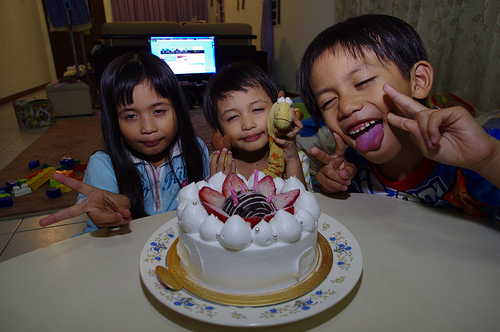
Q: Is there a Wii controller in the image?
A: No, there are no Wii controllers.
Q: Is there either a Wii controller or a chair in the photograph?
A: No, there are no Wii controllers or chairs.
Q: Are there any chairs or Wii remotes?
A: No, there are no Wii remotes or chairs.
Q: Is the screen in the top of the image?
A: Yes, the screen is in the top of the image.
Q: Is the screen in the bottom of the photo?
A: No, the screen is in the top of the image.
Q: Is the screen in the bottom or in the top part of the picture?
A: The screen is in the top of the image.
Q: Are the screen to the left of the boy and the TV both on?
A: Yes, both the screen and the TV are on.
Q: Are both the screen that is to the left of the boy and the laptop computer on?
A: Yes, both the screen and the laptop computer are on.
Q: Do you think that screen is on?
A: Yes, the screen is on.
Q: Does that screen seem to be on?
A: Yes, the screen is on.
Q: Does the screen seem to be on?
A: Yes, the screen is on.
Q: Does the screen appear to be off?
A: No, the screen is on.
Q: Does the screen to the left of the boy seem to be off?
A: No, the screen is on.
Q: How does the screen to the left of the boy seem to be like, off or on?
A: The screen is on.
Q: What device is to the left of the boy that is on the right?
A: The device is a screen.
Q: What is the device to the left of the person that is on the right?
A: The device is a screen.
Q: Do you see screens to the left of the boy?
A: Yes, there is a screen to the left of the boy.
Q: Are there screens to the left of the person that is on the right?
A: Yes, there is a screen to the left of the boy.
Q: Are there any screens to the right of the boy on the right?
A: No, the screen is to the left of the boy.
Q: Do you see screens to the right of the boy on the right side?
A: No, the screen is to the left of the boy.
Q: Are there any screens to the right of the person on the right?
A: No, the screen is to the left of the boy.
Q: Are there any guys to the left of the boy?
A: No, there is a screen to the left of the boy.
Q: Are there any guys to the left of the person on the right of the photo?
A: No, there is a screen to the left of the boy.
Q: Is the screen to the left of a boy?
A: Yes, the screen is to the left of a boy.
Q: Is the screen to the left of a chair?
A: No, the screen is to the left of a boy.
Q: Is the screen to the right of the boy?
A: No, the screen is to the left of the boy.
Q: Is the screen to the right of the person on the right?
A: No, the screen is to the left of the boy.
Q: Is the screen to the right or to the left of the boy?
A: The screen is to the left of the boy.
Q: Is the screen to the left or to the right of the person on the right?
A: The screen is to the left of the boy.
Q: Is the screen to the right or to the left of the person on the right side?
A: The screen is to the left of the boy.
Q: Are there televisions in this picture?
A: Yes, there is a television.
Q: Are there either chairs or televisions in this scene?
A: Yes, there is a television.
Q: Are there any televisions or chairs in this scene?
A: Yes, there is a television.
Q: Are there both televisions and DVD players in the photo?
A: No, there is a television but no DVD players.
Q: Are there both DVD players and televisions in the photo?
A: No, there is a television but no DVD players.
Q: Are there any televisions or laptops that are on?
A: Yes, the television is on.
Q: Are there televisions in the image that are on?
A: Yes, there is a television that is on.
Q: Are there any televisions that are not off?
A: Yes, there is a television that is on.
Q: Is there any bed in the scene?
A: No, there are no beds.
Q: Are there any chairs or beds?
A: No, there are no beds or chairs.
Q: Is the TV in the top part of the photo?
A: Yes, the TV is in the top of the image.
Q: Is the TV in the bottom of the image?
A: No, the TV is in the top of the image.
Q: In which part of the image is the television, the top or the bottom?
A: The television is in the top of the image.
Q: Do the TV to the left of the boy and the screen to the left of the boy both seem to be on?
A: Yes, both the TV and the screen are on.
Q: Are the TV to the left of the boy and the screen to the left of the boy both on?
A: Yes, both the TV and the screen are on.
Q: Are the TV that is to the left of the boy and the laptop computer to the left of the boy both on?
A: Yes, both the television and the laptop are on.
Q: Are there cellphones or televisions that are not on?
A: No, there is a television but it is on.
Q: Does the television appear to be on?
A: Yes, the television is on.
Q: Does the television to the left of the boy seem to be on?
A: Yes, the TV is on.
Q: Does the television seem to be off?
A: No, the television is on.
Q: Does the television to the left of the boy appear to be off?
A: No, the television is on.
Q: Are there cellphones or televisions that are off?
A: No, there is a television but it is on.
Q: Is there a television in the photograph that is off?
A: No, there is a television but it is on.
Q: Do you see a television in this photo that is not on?
A: No, there is a television but it is on.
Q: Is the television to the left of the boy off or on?
A: The television is on.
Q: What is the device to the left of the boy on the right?
A: The device is a television.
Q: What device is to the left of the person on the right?
A: The device is a television.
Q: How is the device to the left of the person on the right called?
A: The device is a television.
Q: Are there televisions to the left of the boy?
A: Yes, there is a television to the left of the boy.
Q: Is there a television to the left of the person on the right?
A: Yes, there is a television to the left of the boy.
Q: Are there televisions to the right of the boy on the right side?
A: No, the television is to the left of the boy.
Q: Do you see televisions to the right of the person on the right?
A: No, the television is to the left of the boy.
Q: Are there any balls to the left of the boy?
A: No, there is a television to the left of the boy.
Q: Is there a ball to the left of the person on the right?
A: No, there is a television to the left of the boy.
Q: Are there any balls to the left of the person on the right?
A: No, there is a television to the left of the boy.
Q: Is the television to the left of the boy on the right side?
A: Yes, the television is to the left of the boy.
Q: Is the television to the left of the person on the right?
A: Yes, the television is to the left of the boy.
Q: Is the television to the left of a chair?
A: No, the television is to the left of the boy.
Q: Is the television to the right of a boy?
A: No, the television is to the left of a boy.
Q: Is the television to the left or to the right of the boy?
A: The television is to the left of the boy.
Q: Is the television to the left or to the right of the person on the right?
A: The television is to the left of the boy.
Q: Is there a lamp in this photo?
A: No, there are no lamps.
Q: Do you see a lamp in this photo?
A: No, there are no lamps.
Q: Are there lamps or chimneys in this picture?
A: No, there are no lamps or chimneys.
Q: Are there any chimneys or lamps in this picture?
A: No, there are no lamps or chimneys.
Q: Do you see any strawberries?
A: Yes, there are strawberries.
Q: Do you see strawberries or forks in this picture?
A: Yes, there are strawberries.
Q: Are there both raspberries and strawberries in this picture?
A: No, there are strawberries but no raspberries.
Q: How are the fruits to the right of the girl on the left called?
A: The fruits are strawberries.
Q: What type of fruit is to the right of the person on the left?
A: The fruits are strawberries.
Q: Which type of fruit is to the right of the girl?
A: The fruits are strawberries.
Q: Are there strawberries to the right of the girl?
A: Yes, there are strawberries to the right of the girl.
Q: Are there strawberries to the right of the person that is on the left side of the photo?
A: Yes, there are strawberries to the right of the girl.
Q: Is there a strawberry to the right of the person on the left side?
A: Yes, there are strawberries to the right of the girl.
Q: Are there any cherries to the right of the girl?
A: No, there are strawberries to the right of the girl.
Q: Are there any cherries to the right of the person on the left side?
A: No, there are strawberries to the right of the girl.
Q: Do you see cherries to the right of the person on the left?
A: No, there are strawberries to the right of the girl.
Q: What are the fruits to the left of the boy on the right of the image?
A: The fruits are strawberries.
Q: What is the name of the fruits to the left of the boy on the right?
A: The fruits are strawberries.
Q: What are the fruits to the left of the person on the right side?
A: The fruits are strawberries.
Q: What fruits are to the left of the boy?
A: The fruits are strawberries.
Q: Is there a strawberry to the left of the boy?
A: Yes, there are strawberries to the left of the boy.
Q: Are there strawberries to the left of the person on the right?
A: Yes, there are strawberries to the left of the boy.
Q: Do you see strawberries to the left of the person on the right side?
A: Yes, there are strawberries to the left of the boy.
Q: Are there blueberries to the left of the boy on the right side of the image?
A: No, there are strawberries to the left of the boy.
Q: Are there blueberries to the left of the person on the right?
A: No, there are strawberries to the left of the boy.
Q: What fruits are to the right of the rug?
A: The fruits are strawberries.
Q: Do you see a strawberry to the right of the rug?
A: Yes, there are strawberries to the right of the rug.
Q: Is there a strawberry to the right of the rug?
A: Yes, there are strawberries to the right of the rug.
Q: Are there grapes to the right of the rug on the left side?
A: No, there are strawberries to the right of the rug.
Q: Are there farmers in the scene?
A: No, there are no farmers.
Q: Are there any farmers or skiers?
A: No, there are no farmers or skiers.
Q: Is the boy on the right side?
A: Yes, the boy is on the right of the image.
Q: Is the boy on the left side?
A: No, the boy is on the right of the image.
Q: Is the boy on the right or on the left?
A: The boy is on the right of the image.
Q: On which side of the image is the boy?
A: The boy is on the right of the image.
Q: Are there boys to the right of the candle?
A: Yes, there is a boy to the right of the candle.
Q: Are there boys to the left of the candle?
A: No, the boy is to the right of the candle.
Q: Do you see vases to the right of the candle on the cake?
A: No, there is a boy to the right of the candle.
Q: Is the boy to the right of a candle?
A: Yes, the boy is to the right of a candle.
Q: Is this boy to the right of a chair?
A: No, the boy is to the right of a candle.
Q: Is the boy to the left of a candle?
A: No, the boy is to the right of a candle.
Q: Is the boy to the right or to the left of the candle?
A: The boy is to the right of the candle.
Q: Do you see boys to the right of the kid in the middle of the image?
A: Yes, there is a boy to the right of the child.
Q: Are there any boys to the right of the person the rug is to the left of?
A: Yes, there is a boy to the right of the child.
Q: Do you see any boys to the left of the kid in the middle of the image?
A: No, the boy is to the right of the child.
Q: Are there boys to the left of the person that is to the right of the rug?
A: No, the boy is to the right of the child.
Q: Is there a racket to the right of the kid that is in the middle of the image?
A: No, there is a boy to the right of the child.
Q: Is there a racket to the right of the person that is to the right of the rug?
A: No, there is a boy to the right of the child.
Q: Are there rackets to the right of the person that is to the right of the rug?
A: No, there is a boy to the right of the child.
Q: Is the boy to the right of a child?
A: Yes, the boy is to the right of a child.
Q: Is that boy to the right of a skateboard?
A: No, the boy is to the right of a child.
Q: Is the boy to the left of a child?
A: No, the boy is to the right of a child.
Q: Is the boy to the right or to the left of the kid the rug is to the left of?
A: The boy is to the right of the kid.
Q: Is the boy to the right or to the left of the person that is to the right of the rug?
A: The boy is to the right of the kid.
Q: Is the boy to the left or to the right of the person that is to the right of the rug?
A: The boy is to the right of the kid.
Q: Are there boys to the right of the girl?
A: Yes, there is a boy to the right of the girl.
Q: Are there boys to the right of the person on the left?
A: Yes, there is a boy to the right of the girl.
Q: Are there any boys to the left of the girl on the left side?
A: No, the boy is to the right of the girl.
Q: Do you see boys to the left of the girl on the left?
A: No, the boy is to the right of the girl.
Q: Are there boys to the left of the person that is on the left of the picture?
A: No, the boy is to the right of the girl.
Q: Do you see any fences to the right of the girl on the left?
A: No, there is a boy to the right of the girl.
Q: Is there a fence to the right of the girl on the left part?
A: No, there is a boy to the right of the girl.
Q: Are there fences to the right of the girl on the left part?
A: No, there is a boy to the right of the girl.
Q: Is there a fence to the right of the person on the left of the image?
A: No, there is a boy to the right of the girl.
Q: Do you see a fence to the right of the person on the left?
A: No, there is a boy to the right of the girl.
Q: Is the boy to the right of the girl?
A: Yes, the boy is to the right of the girl.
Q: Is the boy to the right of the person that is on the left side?
A: Yes, the boy is to the right of the girl.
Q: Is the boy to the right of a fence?
A: No, the boy is to the right of the girl.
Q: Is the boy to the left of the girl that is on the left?
A: No, the boy is to the right of the girl.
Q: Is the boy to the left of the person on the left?
A: No, the boy is to the right of the girl.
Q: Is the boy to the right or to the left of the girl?
A: The boy is to the right of the girl.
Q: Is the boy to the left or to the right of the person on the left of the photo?
A: The boy is to the right of the girl.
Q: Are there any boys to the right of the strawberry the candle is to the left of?
A: Yes, there is a boy to the right of the strawberry.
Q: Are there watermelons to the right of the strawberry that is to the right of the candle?
A: No, there is a boy to the right of the strawberry.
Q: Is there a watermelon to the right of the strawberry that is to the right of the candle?
A: No, there is a boy to the right of the strawberry.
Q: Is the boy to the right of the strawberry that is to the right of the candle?
A: Yes, the boy is to the right of the strawberry.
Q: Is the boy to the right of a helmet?
A: No, the boy is to the right of the strawberry.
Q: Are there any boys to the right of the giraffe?
A: Yes, there is a boy to the right of the giraffe.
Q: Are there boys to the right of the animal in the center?
A: Yes, there is a boy to the right of the giraffe.